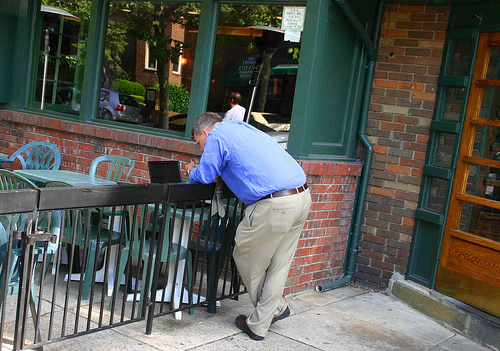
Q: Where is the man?
A: In front of the building.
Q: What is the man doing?
A: Leaning over.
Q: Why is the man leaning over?
A: To look at a laptop.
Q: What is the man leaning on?
A: A fence.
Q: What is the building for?
A: A restaurant.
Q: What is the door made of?
A: Wood.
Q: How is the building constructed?
A: Bricks.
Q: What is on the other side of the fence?
A: Tables.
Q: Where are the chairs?
A: By the tables.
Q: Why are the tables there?
A: For eating.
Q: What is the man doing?
A: Looking at a laptop.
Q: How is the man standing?
A: Bent over.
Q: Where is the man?
A: On the sidewalk.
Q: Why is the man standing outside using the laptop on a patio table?
A: Restaurant is full of guest.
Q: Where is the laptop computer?
A: Blue patio table.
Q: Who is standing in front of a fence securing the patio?
A: A man in a blue shirt.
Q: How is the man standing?
A: Left crossed over the right leg.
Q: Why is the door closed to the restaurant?
A: Locked before business hours.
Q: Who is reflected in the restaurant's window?
A: Man in white shirt.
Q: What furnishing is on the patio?
A: Green tables and chairs.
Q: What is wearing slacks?
A: The man.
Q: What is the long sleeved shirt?
A: Blue.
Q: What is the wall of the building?
A: Green.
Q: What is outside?
A: The green chairs and the table.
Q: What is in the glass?
A: The reflection.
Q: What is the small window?
A: Green.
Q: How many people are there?
A: 1.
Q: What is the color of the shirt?
A: Blue.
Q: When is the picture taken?
A: Daytime.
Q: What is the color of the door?
A: Brown.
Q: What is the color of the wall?
A: Red.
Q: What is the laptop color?
A: Black.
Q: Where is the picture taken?
A: On the sidewalk.